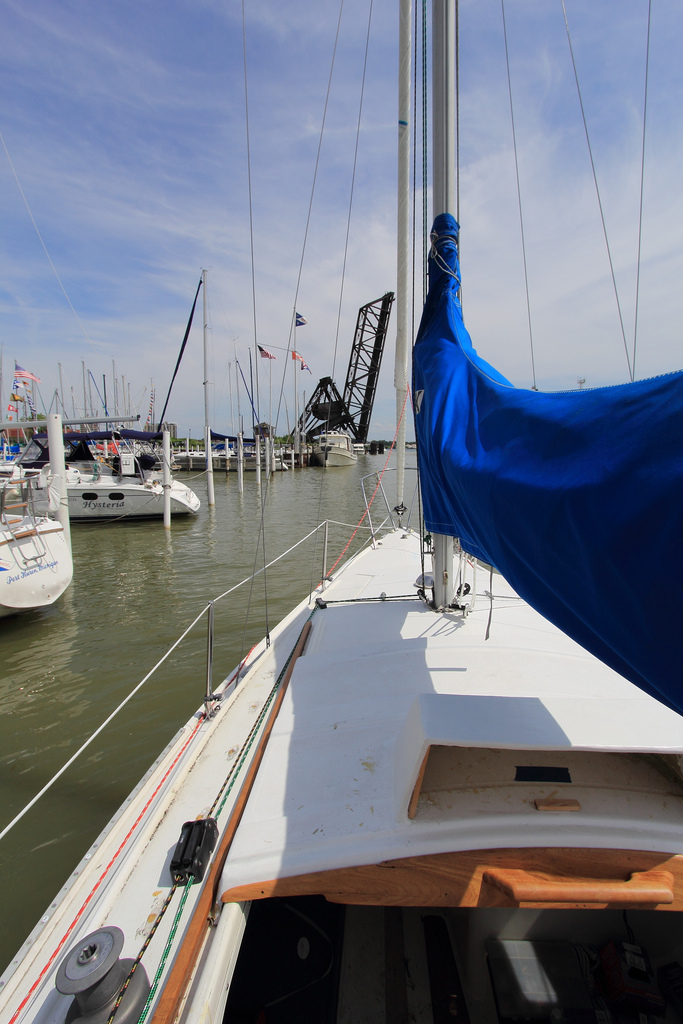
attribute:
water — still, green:
[88, 572, 149, 621]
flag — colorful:
[250, 342, 277, 368]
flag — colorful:
[288, 304, 310, 334]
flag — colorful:
[286, 347, 304, 364]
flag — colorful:
[300, 357, 312, 378]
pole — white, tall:
[40, 408, 74, 542]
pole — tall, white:
[159, 425, 173, 530]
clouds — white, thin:
[6, 6, 660, 441]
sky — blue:
[7, 3, 661, 442]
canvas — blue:
[407, 212, 661, 709]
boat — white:
[0, 511, 74, 609]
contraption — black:
[161, 815, 220, 888]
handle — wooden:
[480, 866, 661, 924]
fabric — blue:
[410, 204, 660, 706]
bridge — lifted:
[337, 286, 397, 447]